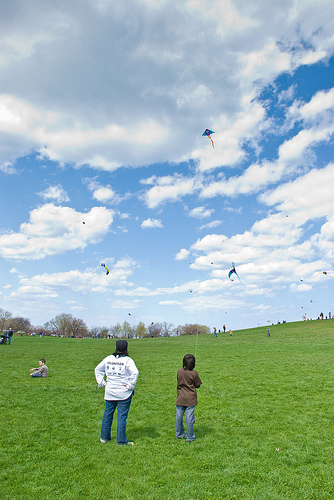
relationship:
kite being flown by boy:
[201, 125, 217, 149] [174, 353, 203, 443]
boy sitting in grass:
[30, 356, 51, 379] [0, 317, 333, 500]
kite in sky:
[201, 125, 217, 149] [0, 1, 332, 338]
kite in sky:
[99, 262, 110, 276] [0, 1, 332, 338]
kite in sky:
[225, 265, 244, 282] [0, 1, 332, 338]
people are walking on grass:
[6, 311, 334, 345] [0, 317, 333, 500]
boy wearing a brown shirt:
[174, 353, 203, 443] [174, 366, 201, 411]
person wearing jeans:
[93, 339, 140, 448] [102, 389, 134, 448]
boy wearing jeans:
[174, 353, 203, 443] [177, 401, 199, 442]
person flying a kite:
[93, 339, 140, 448] [201, 125, 217, 149]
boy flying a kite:
[174, 353, 203, 443] [201, 125, 217, 149]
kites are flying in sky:
[98, 126, 244, 283] [0, 1, 332, 338]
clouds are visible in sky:
[7, 1, 333, 311] [0, 1, 332, 338]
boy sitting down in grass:
[30, 356, 51, 379] [0, 317, 333, 500]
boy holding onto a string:
[174, 353, 203, 443] [194, 273, 201, 373]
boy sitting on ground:
[30, 356, 51, 379] [3, 316, 332, 500]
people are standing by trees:
[6, 311, 334, 345] [0, 309, 209, 340]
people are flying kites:
[6, 311, 334, 345] [19, 128, 333, 318]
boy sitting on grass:
[30, 356, 51, 379] [0, 317, 333, 500]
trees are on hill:
[0, 309, 209, 340] [3, 312, 333, 346]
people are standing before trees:
[6, 311, 334, 345] [0, 309, 209, 340]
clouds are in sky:
[7, 1, 333, 311] [0, 1, 332, 338]